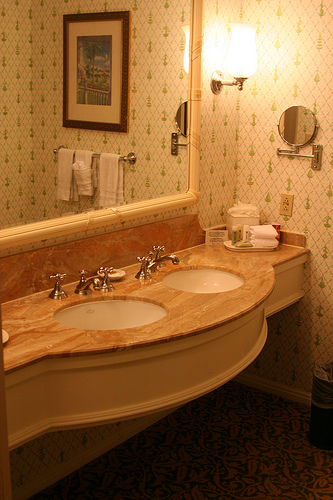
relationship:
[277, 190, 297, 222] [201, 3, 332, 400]
outlet on wall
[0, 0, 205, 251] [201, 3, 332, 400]
mirror on wall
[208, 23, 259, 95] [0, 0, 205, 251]
light beside mirror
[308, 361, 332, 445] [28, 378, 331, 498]
trash on floor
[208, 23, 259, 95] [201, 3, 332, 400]
light on wall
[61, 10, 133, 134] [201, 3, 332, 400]
picture on wall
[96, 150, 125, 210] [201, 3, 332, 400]
towel on wall